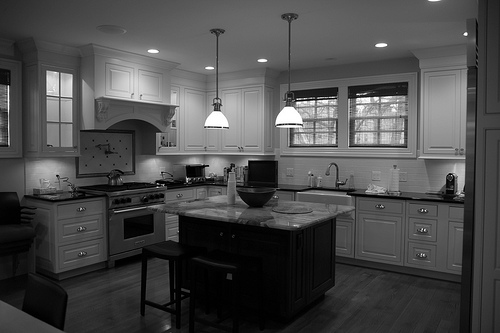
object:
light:
[203, 66, 217, 71]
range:
[105, 188, 172, 208]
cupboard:
[416, 67, 464, 157]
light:
[373, 41, 386, 48]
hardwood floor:
[1, 232, 465, 331]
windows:
[346, 80, 412, 148]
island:
[145, 194, 357, 332]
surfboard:
[196, 11, 317, 143]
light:
[460, 30, 470, 36]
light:
[145, 49, 160, 55]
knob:
[77, 206, 87, 213]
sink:
[292, 161, 357, 197]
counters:
[345, 183, 465, 205]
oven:
[107, 189, 175, 257]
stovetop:
[73, 173, 168, 195]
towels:
[388, 163, 401, 196]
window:
[287, 86, 340, 147]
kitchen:
[0, 0, 498, 331]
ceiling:
[0, 2, 484, 76]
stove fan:
[81, 45, 180, 135]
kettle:
[104, 168, 124, 188]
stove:
[76, 181, 171, 268]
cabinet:
[159, 187, 201, 244]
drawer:
[160, 188, 199, 203]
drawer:
[408, 216, 438, 242]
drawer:
[403, 238, 439, 268]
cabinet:
[26, 189, 109, 280]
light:
[255, 58, 270, 63]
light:
[273, 106, 304, 129]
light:
[203, 109, 228, 131]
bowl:
[236, 186, 276, 208]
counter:
[203, 176, 314, 192]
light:
[426, 0, 443, 3]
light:
[95, 25, 127, 37]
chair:
[140, 239, 183, 329]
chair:
[181, 252, 249, 331]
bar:
[146, 194, 357, 231]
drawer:
[55, 197, 107, 222]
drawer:
[57, 212, 105, 242]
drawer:
[55, 237, 103, 269]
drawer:
[357, 198, 405, 214]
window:
[40, 65, 81, 154]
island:
[351, 184, 466, 283]